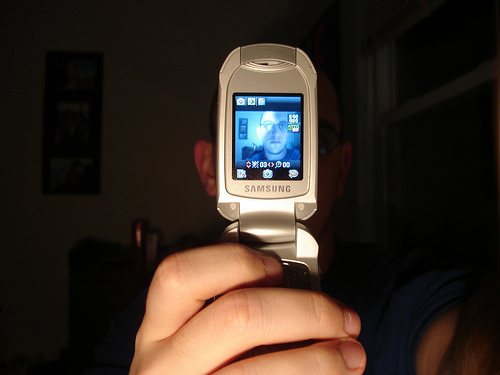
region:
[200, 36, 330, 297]
an open flip phone.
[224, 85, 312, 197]
a screen on a flip phone.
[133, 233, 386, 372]
a hand holding a phone.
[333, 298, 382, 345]
a middle finger nail.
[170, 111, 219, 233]
the side of a human head.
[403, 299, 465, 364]
a hand holding nothing.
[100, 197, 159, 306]
a light in the distance.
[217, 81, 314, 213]
a lcd screen.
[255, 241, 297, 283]
a pointer finger nail.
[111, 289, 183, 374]
a white knuckle.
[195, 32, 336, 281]
open flip phone in hand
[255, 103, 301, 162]
man's face on phone screen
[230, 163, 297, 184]
icons on phone screen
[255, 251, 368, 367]
nails on finger tips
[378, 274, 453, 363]
sleeve of blue shirt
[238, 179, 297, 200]
name of phone company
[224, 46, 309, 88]
silver surface of phone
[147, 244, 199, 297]
knuckle of bent finger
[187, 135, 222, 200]
ear behind open phone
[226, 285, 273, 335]
lines on middle knuckle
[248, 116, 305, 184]
part of a screen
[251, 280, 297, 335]
part of a finger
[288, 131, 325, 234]
edge of a screen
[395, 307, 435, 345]
edge of a sleeve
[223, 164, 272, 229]
part of a phone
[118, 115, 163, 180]
part of a wall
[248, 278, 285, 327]
part of a findge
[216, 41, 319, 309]
silver Samsung flip phone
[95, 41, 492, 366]
man taking a picture of himself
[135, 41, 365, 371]
man's hand holding phone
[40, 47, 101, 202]
Frame with three pictures hanging on wall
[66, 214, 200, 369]
dresser with stuff all over top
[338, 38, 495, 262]
window with white frame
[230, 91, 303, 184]
screen on inside of flip phone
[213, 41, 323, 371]
cell phone is flipped open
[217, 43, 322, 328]
cell phone camera is on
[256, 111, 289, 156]
man with glasses in screen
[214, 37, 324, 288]
a flip top phone selfie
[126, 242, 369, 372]
fingers are on the phone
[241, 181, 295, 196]
a logo is on the phone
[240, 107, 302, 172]
a picture of the owner of the phone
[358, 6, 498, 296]
a window is behind the man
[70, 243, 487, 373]
the person has a blue t-shirt on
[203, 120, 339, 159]
the person is wearing glasses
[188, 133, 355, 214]
the ears on the phone owner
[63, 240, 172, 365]
a cabinet is behind the man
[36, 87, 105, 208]
a picture is on the wall